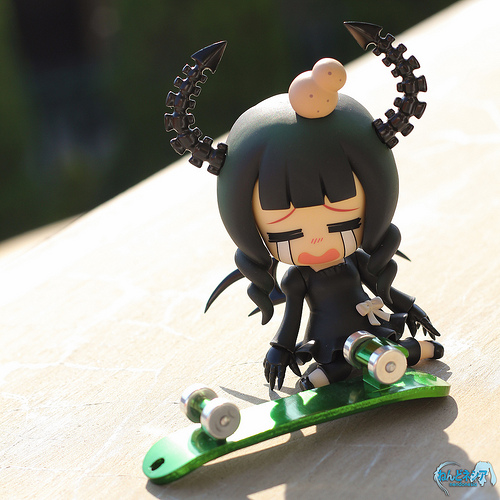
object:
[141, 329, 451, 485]
skateboard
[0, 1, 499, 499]
table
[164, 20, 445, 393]
figure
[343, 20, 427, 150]
horns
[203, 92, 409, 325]
hair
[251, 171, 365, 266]
face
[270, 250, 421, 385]
clothing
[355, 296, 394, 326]
bow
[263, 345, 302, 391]
gloves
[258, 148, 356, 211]
bang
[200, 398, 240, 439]
wheel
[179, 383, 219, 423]
wheel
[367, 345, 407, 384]
wheel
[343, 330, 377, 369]
wheel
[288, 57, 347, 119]
knot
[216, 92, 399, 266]
head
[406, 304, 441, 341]
hand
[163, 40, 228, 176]
horn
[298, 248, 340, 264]
mouth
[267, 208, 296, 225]
eyebrows